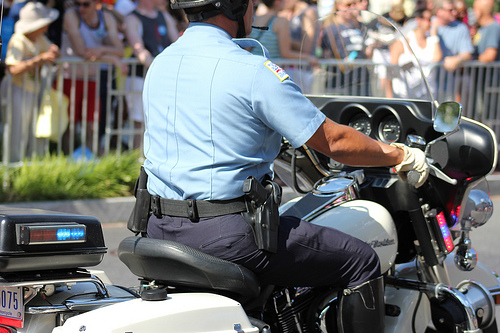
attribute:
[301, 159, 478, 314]
bike — White, Black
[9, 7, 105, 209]
person — Standing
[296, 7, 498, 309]
motorcycle — Riding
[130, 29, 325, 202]
shirt — blue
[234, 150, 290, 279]
gun — Holstered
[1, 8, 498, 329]
motorcycle — Riding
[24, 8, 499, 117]
people — Standing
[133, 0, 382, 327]
man — Riding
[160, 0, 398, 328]
cop — Riding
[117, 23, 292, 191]
shirt — blue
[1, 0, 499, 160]
spectators — Spectating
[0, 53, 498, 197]
metal fence — temporary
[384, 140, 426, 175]
glove — white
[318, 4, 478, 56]
people — Standing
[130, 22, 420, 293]
an officer — Riding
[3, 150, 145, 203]
grass — Green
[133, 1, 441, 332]
cop — Riding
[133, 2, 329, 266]
officer — police officer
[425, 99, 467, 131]
mirror — Clear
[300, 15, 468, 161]
windshield — Clear